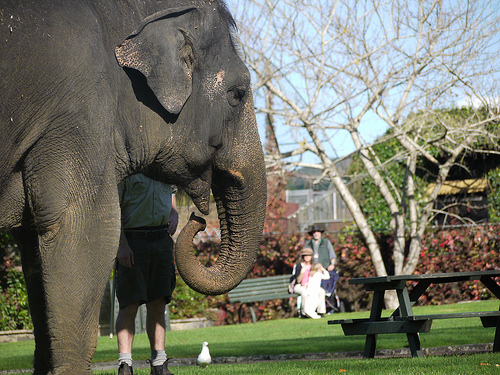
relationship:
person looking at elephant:
[290, 246, 330, 321] [1, 1, 270, 374]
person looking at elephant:
[297, 224, 341, 314] [1, 1, 270, 374]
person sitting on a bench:
[290, 246, 330, 321] [224, 270, 338, 324]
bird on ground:
[195, 339, 214, 370] [1, 300, 500, 374]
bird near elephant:
[195, 339, 214, 370] [1, 1, 270, 374]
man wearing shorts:
[107, 161, 181, 375] [113, 223, 179, 309]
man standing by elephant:
[107, 161, 181, 375] [1, 1, 270, 374]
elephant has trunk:
[1, 1, 270, 374] [173, 161, 267, 299]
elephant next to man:
[1, 1, 270, 374] [107, 161, 181, 375]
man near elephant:
[107, 161, 181, 375] [1, 1, 270, 374]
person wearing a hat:
[290, 246, 330, 321] [300, 246, 315, 258]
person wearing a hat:
[297, 224, 341, 314] [308, 222, 327, 235]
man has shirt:
[107, 161, 181, 375] [113, 169, 179, 232]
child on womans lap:
[308, 263, 331, 300] [293, 281, 328, 298]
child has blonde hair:
[308, 263, 331, 300] [309, 261, 323, 277]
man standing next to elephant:
[107, 161, 181, 375] [1, 1, 270, 374]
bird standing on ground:
[195, 339, 214, 370] [1, 300, 500, 374]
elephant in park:
[1, 1, 270, 374] [1, 196, 499, 374]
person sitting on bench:
[290, 246, 330, 321] [224, 270, 338, 324]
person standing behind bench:
[297, 224, 341, 314] [224, 270, 338, 324]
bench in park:
[224, 270, 338, 324] [1, 196, 499, 374]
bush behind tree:
[193, 220, 497, 327] [205, 0, 499, 316]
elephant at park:
[1, 1, 270, 374] [1, 196, 499, 374]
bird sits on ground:
[195, 339, 214, 370] [1, 300, 500, 374]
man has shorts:
[107, 161, 181, 375] [113, 223, 179, 309]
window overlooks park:
[430, 194, 491, 226] [1, 196, 499, 374]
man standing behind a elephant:
[107, 161, 181, 375] [1, 1, 270, 374]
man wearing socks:
[107, 161, 181, 375] [113, 345, 174, 368]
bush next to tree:
[193, 220, 497, 327] [205, 0, 499, 316]